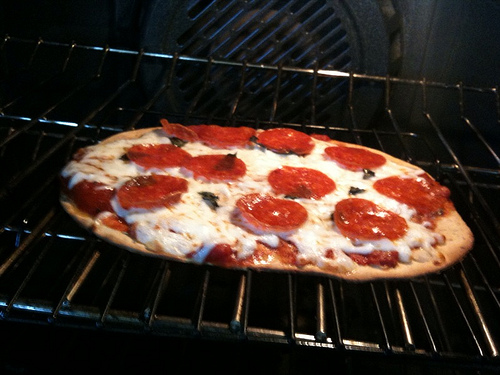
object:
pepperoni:
[269, 161, 337, 196]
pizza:
[55, 118, 474, 282]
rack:
[0, 32, 496, 366]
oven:
[1, 1, 499, 374]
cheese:
[64, 125, 456, 271]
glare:
[367, 211, 390, 218]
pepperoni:
[334, 196, 406, 239]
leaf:
[200, 190, 221, 210]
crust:
[58, 126, 475, 282]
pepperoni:
[159, 117, 206, 144]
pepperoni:
[196, 122, 255, 148]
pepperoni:
[125, 143, 194, 170]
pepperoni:
[180, 154, 249, 184]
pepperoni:
[258, 125, 314, 156]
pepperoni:
[324, 146, 387, 171]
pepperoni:
[375, 172, 451, 216]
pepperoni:
[118, 173, 190, 209]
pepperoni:
[236, 190, 308, 232]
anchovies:
[215, 152, 238, 171]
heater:
[139, 2, 390, 149]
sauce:
[70, 177, 116, 221]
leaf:
[284, 194, 300, 201]